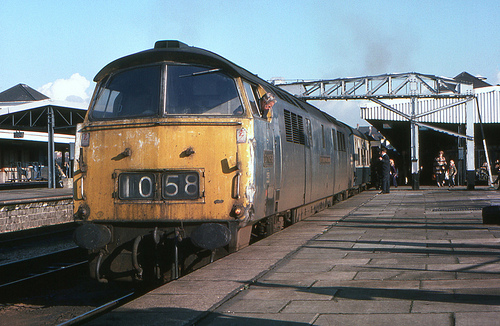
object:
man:
[376, 146, 392, 194]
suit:
[379, 152, 391, 194]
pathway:
[0, 184, 76, 210]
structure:
[273, 70, 480, 101]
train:
[70, 39, 392, 294]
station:
[0, 81, 91, 210]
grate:
[282, 107, 308, 147]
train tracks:
[0, 256, 145, 324]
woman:
[431, 150, 448, 188]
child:
[445, 158, 457, 189]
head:
[256, 89, 278, 111]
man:
[231, 91, 278, 122]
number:
[123, 175, 131, 199]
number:
[137, 175, 153, 198]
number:
[163, 172, 180, 197]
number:
[183, 172, 198, 196]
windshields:
[161, 63, 247, 116]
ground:
[0, 239, 155, 325]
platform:
[76, 184, 500, 326]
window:
[160, 63, 248, 115]